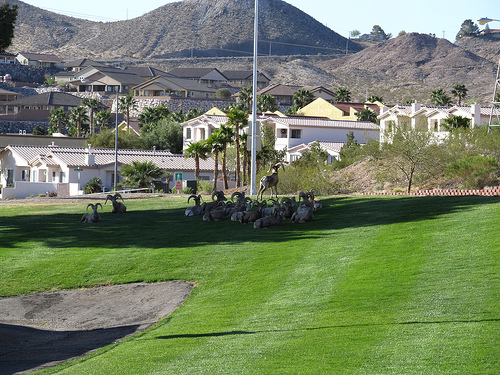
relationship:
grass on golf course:
[338, 197, 395, 243] [5, 102, 482, 370]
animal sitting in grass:
[105, 191, 127, 214] [92, 209, 165, 243]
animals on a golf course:
[256, 162, 285, 201] [1, 192, 499, 373]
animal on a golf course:
[80, 203, 103, 224] [1, 192, 499, 373]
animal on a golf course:
[105, 191, 127, 214] [1, 192, 499, 373]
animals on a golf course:
[184, 191, 323, 230] [1, 192, 499, 373]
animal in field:
[78, 200, 103, 225] [2, 187, 497, 374]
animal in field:
[103, 190, 125, 215] [2, 187, 497, 374]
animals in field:
[184, 191, 323, 230] [2, 187, 497, 374]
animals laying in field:
[85, 154, 334, 234] [2, 187, 497, 374]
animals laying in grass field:
[176, 188, 324, 235] [142, 198, 375, 313]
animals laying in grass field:
[184, 191, 323, 230] [116, 221, 420, 282]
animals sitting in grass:
[184, 191, 323, 230] [3, 195, 498, 373]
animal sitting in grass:
[105, 191, 127, 214] [3, 195, 498, 373]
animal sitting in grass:
[80, 203, 103, 224] [3, 195, 498, 373]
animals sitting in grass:
[256, 162, 285, 201] [3, 195, 498, 373]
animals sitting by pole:
[184, 191, 323, 230] [227, 12, 263, 219]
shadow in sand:
[1, 308, 166, 373] [7, 276, 197, 355]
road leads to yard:
[0, 278, 187, 373] [9, 250, 484, 369]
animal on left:
[105, 191, 127, 214] [1, 2, 86, 366]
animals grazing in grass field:
[184, 191, 323, 230] [179, 223, 345, 283]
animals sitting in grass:
[184, 191, 323, 230] [378, 288, 418, 348]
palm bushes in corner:
[114, 160, 169, 194] [85, 169, 186, 197]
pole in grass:
[245, 2, 261, 201] [3, 195, 498, 373]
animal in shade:
[80, 203, 103, 224] [1, 193, 499, 248]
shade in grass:
[0, 193, 499, 249] [62, 152, 484, 358]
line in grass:
[157, 192, 491, 373] [3, 195, 498, 373]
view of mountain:
[3, 1, 499, 367] [5, 0, 499, 99]